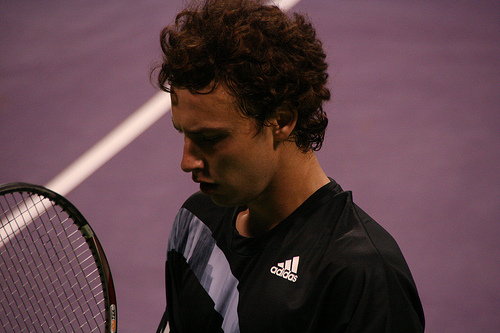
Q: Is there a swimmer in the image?
A: No, there are no swimmers.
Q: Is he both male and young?
A: Yes, the player is male and young.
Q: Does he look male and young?
A: Yes, the player is male and young.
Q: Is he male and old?
A: No, the player is male but young.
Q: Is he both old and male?
A: No, the player is male but young.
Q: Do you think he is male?
A: Yes, the player is male.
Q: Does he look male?
A: Yes, the player is male.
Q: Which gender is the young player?
A: The player is male.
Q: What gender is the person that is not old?
A: The player is male.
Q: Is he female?
A: No, the player is male.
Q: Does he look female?
A: No, the player is male.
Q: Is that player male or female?
A: The player is male.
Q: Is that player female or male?
A: The player is male.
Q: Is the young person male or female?
A: The player is male.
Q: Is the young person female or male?
A: The player is male.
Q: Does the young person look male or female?
A: The player is male.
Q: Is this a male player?
A: Yes, this is a male player.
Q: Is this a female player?
A: No, this is a male player.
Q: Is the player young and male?
A: Yes, the player is young and male.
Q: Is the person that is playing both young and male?
A: Yes, the player is young and male.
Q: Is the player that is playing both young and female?
A: No, the player is young but male.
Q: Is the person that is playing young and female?
A: No, the player is young but male.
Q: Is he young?
A: Yes, the player is young.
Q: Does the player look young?
A: Yes, the player is young.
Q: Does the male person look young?
A: Yes, the player is young.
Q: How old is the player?
A: The player is young.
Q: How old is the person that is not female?
A: The player is young.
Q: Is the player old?
A: No, the player is young.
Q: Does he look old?
A: No, the player is young.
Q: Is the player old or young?
A: The player is young.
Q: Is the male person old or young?
A: The player is young.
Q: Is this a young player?
A: Yes, this is a young player.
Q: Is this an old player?
A: No, this is a young player.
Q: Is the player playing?
A: Yes, the player is playing.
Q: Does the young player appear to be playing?
A: Yes, the player is playing.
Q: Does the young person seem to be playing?
A: Yes, the player is playing.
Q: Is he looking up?
A: No, the player is playing.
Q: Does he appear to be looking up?
A: No, the player is playing.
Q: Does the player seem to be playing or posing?
A: The player is playing.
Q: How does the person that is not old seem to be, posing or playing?
A: The player is playing.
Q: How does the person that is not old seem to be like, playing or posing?
A: The player is playing.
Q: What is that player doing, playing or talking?
A: The player is playing.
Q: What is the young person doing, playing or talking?
A: The player is playing.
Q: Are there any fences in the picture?
A: No, there are no fences.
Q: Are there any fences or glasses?
A: No, there are no fences or glasses.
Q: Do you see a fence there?
A: No, there are no fences.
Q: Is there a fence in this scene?
A: No, there are no fences.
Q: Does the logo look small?
A: Yes, the logo is small.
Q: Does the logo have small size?
A: Yes, the logo is small.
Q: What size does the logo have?
A: The logo has small size.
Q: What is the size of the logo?
A: The logo is small.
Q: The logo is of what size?
A: The logo is small.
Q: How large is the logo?
A: The logo is small.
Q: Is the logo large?
A: No, the logo is small.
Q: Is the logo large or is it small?
A: The logo is small.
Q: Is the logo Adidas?
A: Yes, the logo is adidas.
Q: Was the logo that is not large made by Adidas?
A: Yes, the logo was made by adidas.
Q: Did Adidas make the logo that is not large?
A: Yes, the logo was made by adidas.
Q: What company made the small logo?
A: Adidas made adidas.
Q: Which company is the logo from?
A: The logo is from adidas.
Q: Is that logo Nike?
A: No, the logo is adidas.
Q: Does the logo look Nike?
A: No, the logo is adidas.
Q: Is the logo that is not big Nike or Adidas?
A: The logo is adidas.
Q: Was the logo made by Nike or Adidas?
A: The logo was made adidas.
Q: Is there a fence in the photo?
A: No, there are no fences.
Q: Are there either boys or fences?
A: No, there are no fences or boys.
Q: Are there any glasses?
A: No, there are no glasses.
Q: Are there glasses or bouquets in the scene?
A: No, there are no glasses or bouquets.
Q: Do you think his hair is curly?
A: Yes, the hair is curly.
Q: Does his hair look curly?
A: Yes, the hair is curly.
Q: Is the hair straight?
A: No, the hair is curly.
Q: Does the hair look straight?
A: No, the hair is curly.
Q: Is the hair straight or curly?
A: The hair is curly.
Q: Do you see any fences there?
A: No, there are no fences.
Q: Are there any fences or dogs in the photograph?
A: No, there are no fences or dogs.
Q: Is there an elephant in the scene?
A: No, there are no elephants.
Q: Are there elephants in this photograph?
A: No, there are no elephants.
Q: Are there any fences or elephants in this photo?
A: No, there are no elephants or fences.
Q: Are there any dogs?
A: No, there are no dogs.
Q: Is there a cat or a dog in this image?
A: No, there are no dogs or cats.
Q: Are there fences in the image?
A: No, there are no fences.